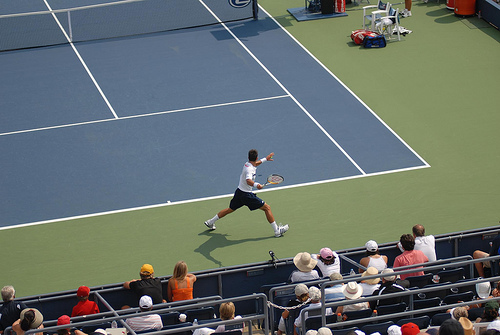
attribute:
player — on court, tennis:
[204, 146, 289, 238]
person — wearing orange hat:
[117, 262, 169, 310]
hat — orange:
[137, 260, 155, 282]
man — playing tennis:
[230, 142, 272, 227]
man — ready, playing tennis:
[204, 149, 289, 238]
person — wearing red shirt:
[70, 286, 100, 315]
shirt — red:
[72, 301, 99, 314]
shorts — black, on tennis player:
[228, 187, 265, 210]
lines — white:
[219, 31, 341, 114]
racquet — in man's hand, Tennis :
[256, 173, 290, 191]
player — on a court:
[215, 144, 302, 241]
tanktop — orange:
[170, 277, 190, 299]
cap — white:
[365, 240, 378, 258]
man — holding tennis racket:
[216, 139, 279, 226]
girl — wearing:
[163, 270, 205, 303]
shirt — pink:
[393, 249, 437, 272]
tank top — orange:
[166, 274, 204, 298]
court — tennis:
[92, 49, 439, 164]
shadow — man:
[196, 230, 277, 255]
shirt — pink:
[394, 251, 427, 281]